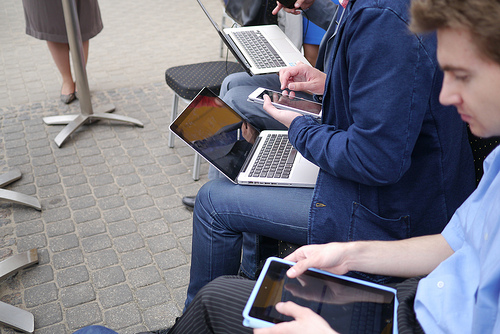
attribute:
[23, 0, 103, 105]
woman — standing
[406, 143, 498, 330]
shirt — light blue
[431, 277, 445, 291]
button — white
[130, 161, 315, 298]
jeans — blue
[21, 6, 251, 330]
walkway — stone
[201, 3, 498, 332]
person — sitting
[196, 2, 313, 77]
laptop — open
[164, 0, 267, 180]
chair — black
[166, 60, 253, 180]
chair — silver, black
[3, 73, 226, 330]
sidewalk — concrete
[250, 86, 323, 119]
tablet computer — mini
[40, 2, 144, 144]
table — metal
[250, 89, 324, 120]
tablet — mini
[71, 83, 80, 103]
shoe — matching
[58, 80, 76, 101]
shoe — matching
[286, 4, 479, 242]
jacket — blue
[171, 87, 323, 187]
laptop — open